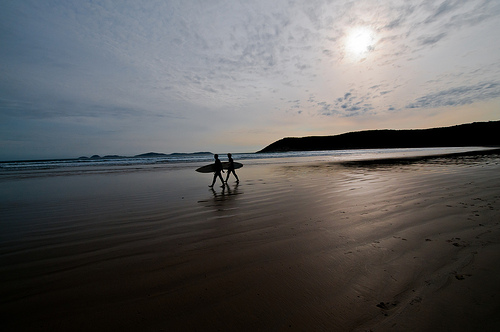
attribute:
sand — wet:
[44, 186, 433, 289]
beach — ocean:
[24, 145, 491, 308]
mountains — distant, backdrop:
[62, 128, 270, 162]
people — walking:
[189, 147, 270, 222]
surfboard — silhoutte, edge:
[189, 164, 249, 181]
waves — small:
[32, 158, 109, 172]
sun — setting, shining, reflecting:
[339, 30, 390, 61]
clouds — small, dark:
[260, 9, 487, 80]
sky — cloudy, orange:
[43, 26, 420, 150]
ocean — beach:
[7, 143, 353, 183]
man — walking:
[207, 149, 227, 197]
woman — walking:
[222, 140, 254, 187]